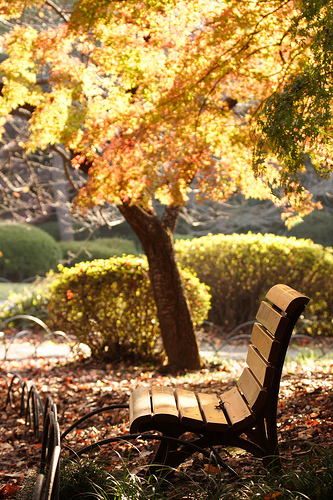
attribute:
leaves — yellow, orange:
[3, 0, 303, 204]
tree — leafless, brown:
[1, 1, 328, 363]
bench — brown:
[122, 275, 313, 492]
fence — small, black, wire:
[0, 369, 65, 499]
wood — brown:
[191, 384, 235, 435]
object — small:
[214, 398, 229, 412]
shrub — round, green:
[0, 221, 62, 279]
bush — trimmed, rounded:
[0, 216, 64, 282]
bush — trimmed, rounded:
[59, 234, 138, 270]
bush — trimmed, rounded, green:
[47, 252, 214, 361]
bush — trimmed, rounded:
[168, 229, 331, 336]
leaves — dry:
[70, 372, 107, 395]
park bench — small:
[123, 278, 310, 490]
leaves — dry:
[1, 232, 332, 498]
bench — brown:
[115, 270, 321, 476]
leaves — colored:
[0, 0, 332, 231]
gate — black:
[11, 371, 42, 418]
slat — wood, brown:
[239, 344, 275, 384]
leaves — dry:
[2, 326, 332, 497]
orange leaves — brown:
[60, 389, 103, 414]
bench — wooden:
[98, 221, 307, 498]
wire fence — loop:
[34, 411, 99, 437]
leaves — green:
[149, 112, 230, 391]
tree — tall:
[3, 35, 308, 373]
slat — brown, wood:
[259, 283, 307, 311]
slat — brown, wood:
[163, 355, 227, 431]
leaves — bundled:
[5, 353, 330, 498]